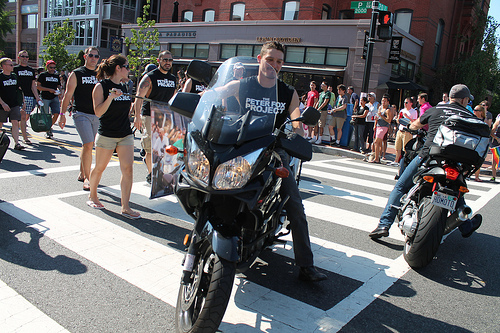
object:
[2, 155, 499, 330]
crosswalk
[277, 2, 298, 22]
window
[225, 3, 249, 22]
window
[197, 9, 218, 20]
window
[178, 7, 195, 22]
window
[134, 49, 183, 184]
man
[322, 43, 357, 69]
window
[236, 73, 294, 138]
shirt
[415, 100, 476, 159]
shirt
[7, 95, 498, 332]
city street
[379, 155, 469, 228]
jeans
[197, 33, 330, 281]
man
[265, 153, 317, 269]
jeans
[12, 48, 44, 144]
person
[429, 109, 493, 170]
bag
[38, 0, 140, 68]
building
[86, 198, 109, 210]
sandals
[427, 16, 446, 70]
small window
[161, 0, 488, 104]
building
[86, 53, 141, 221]
pedestrian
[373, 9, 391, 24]
signal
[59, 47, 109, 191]
pedestrian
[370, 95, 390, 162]
pedestrian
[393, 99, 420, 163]
pedestrian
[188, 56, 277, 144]
small window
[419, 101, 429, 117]
shirt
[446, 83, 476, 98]
hat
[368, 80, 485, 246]
man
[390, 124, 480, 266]
motorcycle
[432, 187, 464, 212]
plate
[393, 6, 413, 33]
window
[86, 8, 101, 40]
windows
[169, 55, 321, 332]
motorcycle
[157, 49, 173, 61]
hair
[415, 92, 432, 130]
man